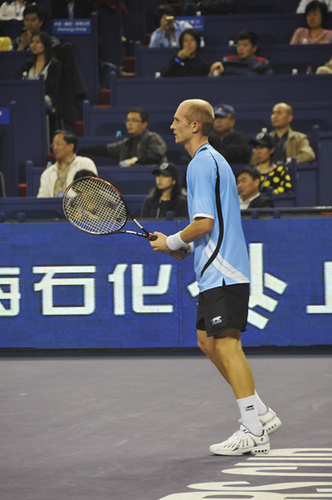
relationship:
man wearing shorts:
[149, 98, 282, 458] [193, 281, 251, 336]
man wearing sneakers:
[149, 98, 282, 458] [258, 409, 280, 429]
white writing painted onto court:
[159, 446, 330, 499] [0, 352, 332, 500]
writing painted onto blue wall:
[108, 258, 177, 315] [0, 220, 332, 348]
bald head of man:
[175, 97, 216, 118] [149, 98, 282, 458]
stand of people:
[1, 1, 330, 223] [0, 0, 330, 218]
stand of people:
[1, 1, 330, 223] [252, 102, 316, 195]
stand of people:
[1, 1, 330, 223] [37, 107, 165, 197]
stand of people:
[1, 1, 330, 223] [20, 7, 68, 137]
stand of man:
[1, 1, 330, 223] [0, 0, 332, 220]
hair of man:
[176, 96, 216, 138] [147, 98, 277, 453]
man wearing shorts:
[147, 98, 277, 453] [193, 281, 251, 336]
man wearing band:
[129, 81, 294, 366] [166, 231, 189, 251]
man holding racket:
[149, 98, 282, 458] [62, 176, 157, 242]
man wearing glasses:
[0, 0, 332, 220] [123, 114, 143, 124]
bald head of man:
[170, 99, 215, 144] [147, 98, 277, 453]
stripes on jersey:
[205, 234, 248, 282] [186, 142, 252, 293]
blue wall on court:
[2, 220, 330, 348] [0, 354, 331, 498]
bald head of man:
[170, 99, 215, 144] [149, 98, 282, 458]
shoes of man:
[196, 408, 288, 460] [149, 98, 282, 458]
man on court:
[149, 98, 282, 458] [0, 354, 331, 498]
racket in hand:
[61, 173, 165, 247] [150, 231, 188, 260]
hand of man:
[150, 231, 188, 260] [149, 98, 282, 458]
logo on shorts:
[213, 315, 222, 324] [193, 281, 251, 336]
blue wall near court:
[0, 220, 332, 348] [0, 352, 332, 500]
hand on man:
[149, 228, 170, 252] [147, 98, 277, 453]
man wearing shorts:
[147, 98, 277, 453] [196, 277, 248, 335]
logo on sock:
[248, 398, 258, 417] [236, 396, 262, 434]